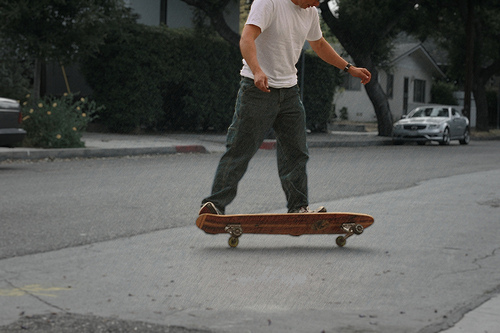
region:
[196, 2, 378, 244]
A man standing on a skateboard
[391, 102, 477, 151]
A silver car parked in the street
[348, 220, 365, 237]
The wheel on a skateboard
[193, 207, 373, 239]
The bottom of a skateboard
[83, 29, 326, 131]
Tall green hedges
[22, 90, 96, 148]
A small plant with yellow flowers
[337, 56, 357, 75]
A black watch on a man's wrist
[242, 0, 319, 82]
A white short-sleeved shirt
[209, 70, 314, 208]
A pair of blue jeans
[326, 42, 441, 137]
A white house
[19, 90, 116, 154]
A BUSH WITH YELLOW FLOWERS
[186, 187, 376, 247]
FEET ON A SKATEBOARD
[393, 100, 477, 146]
SILVER CAR PARKED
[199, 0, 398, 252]
A SKATE BOARDER IN THE STREET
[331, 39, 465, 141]
A WHITE HOUSE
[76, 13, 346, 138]
A ROW OF GREEN BUSHES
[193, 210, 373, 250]
A YELLOW AND RED SKATEBOARD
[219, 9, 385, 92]
A WHITE T SHIRT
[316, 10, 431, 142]
A TREE ON THE SIDEWALK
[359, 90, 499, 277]
A GRAY PAVED ROAD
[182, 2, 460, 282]
a person skateboarding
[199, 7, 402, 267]
a person skateboarding outside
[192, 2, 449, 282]
a person leaning on a skateboard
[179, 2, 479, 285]
a skateboarding wearing a white shirt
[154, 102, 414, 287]
a skateboarder wearing shoes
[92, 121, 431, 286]
a skateboarder leaning with skateboard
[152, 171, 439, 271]
skateboard leaning on its wheels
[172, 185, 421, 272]
a skateboard leaning on two wheels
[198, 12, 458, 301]
a person wearing jeans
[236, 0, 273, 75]
the arm of a person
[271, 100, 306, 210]
the leg of a person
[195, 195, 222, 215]
a shoe on the person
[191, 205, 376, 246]
a brown wooden skateboard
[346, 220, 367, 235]
a gray skateboard wheel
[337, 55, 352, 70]
a black wrist watch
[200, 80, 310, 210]
a pair of blue jeans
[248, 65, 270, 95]
the hand of a person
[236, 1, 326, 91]
a white tee shirt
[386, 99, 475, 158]
a gray car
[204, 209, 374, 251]
red longboard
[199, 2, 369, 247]
Man on a longboard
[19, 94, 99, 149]
Bush with yellow flowers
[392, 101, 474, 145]
Silver sports car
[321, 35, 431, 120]
White A-frame house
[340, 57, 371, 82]
Wristwatch and hand of a man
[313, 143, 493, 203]
Sidewalk and street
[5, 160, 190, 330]
Sidewalk and street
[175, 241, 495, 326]
Sidewalk and shadow of a longboard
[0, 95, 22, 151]
Rear end of a black sedan